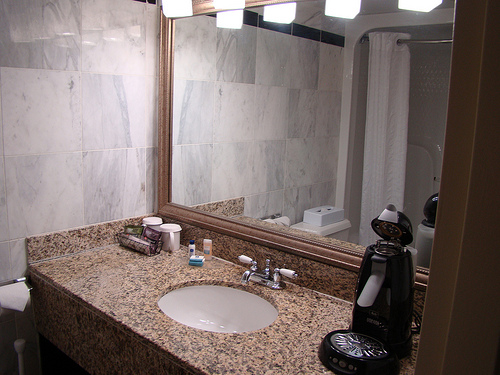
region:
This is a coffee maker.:
[334, 207, 428, 363]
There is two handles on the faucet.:
[238, 250, 305, 294]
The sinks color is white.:
[152, 265, 292, 346]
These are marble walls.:
[7, 4, 139, 209]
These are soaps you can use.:
[186, 235, 212, 268]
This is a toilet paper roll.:
[5, 272, 29, 317]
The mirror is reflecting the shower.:
[163, 10, 451, 245]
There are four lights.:
[210, 2, 445, 32]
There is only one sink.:
[29, 206, 400, 370]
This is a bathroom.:
[4, 2, 490, 365]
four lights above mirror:
[197, 0, 447, 31]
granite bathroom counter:
[23, 212, 425, 372]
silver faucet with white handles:
[233, 246, 299, 289]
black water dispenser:
[316, 201, 423, 371]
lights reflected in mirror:
[196, 1, 466, 29]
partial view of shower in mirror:
[346, 25, 452, 260]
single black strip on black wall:
[161, 5, 343, 57]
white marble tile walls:
[0, 7, 345, 279]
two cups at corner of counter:
[136, 213, 183, 251]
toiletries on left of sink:
[187, 229, 217, 269]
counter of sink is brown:
[21, 208, 375, 373]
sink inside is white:
[158, 282, 282, 332]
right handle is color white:
[268, 264, 302, 291]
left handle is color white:
[228, 251, 259, 272]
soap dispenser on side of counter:
[315, 188, 427, 370]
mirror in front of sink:
[141, 4, 452, 285]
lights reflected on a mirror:
[251, 0, 452, 34]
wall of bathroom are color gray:
[2, 14, 144, 211]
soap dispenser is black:
[314, 201, 424, 373]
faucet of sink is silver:
[244, 267, 271, 289]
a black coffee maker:
[316, 200, 423, 372]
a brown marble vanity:
[23, 197, 430, 373]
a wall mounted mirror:
[150, 1, 456, 290]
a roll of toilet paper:
[2, 276, 34, 318]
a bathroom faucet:
[231, 249, 299, 296]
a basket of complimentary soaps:
[116, 222, 158, 255]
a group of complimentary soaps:
[183, 236, 213, 269]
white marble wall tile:
[5, 0, 154, 246]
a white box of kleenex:
[300, 201, 344, 226]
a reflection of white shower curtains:
[359, 25, 410, 245]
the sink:
[156, 252, 281, 352]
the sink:
[178, 172, 322, 372]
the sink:
[166, 167, 261, 342]